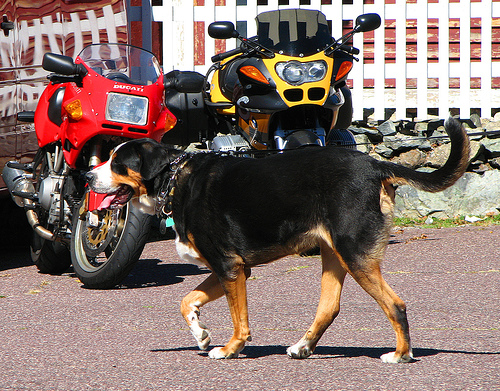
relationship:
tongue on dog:
[101, 192, 115, 217] [74, 121, 473, 363]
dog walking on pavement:
[74, 121, 473, 363] [17, 278, 494, 385]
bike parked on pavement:
[8, 37, 211, 284] [437, 255, 492, 380]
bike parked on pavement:
[161, 6, 381, 237] [437, 255, 492, 380]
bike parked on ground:
[161, 6, 381, 237] [0, 203, 498, 389]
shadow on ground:
[145, 326, 498, 379] [0, 203, 498, 389]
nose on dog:
[82, 171, 97, 182] [74, 121, 473, 363]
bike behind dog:
[189, 0, 381, 155] [74, 121, 473, 363]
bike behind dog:
[8, 37, 211, 284] [74, 121, 473, 363]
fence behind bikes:
[173, 7, 475, 122] [192, 21, 412, 276]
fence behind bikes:
[173, 7, 475, 122] [12, 37, 173, 317]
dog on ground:
[74, 121, 473, 363] [0, 203, 498, 389]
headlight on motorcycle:
[265, 34, 336, 81] [192, 0, 389, 171]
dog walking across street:
[74, 121, 473, 363] [4, 216, 497, 383]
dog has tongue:
[74, 121, 473, 363] [85, 183, 128, 213]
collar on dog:
[155, 146, 198, 228] [74, 121, 473, 363]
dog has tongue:
[83, 116, 470, 363] [97, 178, 127, 217]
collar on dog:
[155, 146, 190, 234] [74, 121, 473, 363]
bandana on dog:
[147, 150, 188, 184] [74, 121, 473, 363]